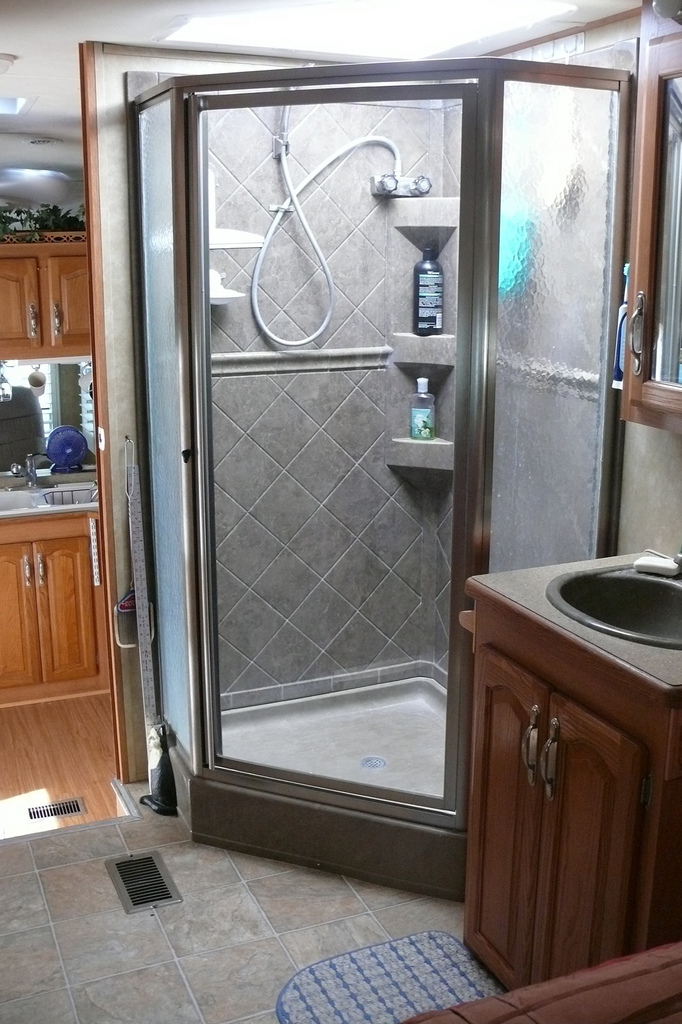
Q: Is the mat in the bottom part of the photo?
A: Yes, the mat is in the bottom of the image.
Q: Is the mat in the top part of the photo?
A: No, the mat is in the bottom of the image.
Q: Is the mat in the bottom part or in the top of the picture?
A: The mat is in the bottom of the image.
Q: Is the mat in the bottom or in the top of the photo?
A: The mat is in the bottom of the image.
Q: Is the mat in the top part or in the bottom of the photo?
A: The mat is in the bottom of the image.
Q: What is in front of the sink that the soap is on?
A: The mat is in front of the sink.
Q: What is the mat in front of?
A: The mat is in front of the sink.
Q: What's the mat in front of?
A: The mat is in front of the sink.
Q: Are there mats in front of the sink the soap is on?
A: Yes, there is a mat in front of the sink.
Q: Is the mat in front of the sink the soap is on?
A: Yes, the mat is in front of the sink.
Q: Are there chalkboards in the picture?
A: No, there are no chalkboards.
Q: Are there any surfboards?
A: No, there are no surfboards.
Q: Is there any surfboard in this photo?
A: No, there are no surfboards.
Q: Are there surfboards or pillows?
A: No, there are no surfboards or pillows.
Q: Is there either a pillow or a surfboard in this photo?
A: No, there are no surfboards or pillows.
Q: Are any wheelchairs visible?
A: No, there are no wheelchairs.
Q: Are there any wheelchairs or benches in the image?
A: No, there are no wheelchairs or benches.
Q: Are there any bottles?
A: Yes, there is a bottle.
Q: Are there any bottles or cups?
A: Yes, there is a bottle.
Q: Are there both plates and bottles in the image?
A: No, there is a bottle but no plates.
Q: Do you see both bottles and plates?
A: No, there is a bottle but no plates.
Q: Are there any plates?
A: No, there are no plates.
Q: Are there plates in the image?
A: No, there are no plates.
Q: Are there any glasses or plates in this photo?
A: No, there are no plates or glasses.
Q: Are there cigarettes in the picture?
A: No, there are no cigarettes.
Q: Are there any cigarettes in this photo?
A: No, there are no cigarettes.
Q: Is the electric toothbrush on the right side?
A: Yes, the electric toothbrush is on the right of the image.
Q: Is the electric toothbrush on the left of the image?
A: No, the electric toothbrush is on the right of the image.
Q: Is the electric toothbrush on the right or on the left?
A: The electric toothbrush is on the right of the image.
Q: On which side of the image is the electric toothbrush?
A: The electric toothbrush is on the right of the image.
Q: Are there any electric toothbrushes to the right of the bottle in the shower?
A: Yes, there is an electric toothbrush to the right of the bottle.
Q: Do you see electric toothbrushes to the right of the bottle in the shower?
A: Yes, there is an electric toothbrush to the right of the bottle.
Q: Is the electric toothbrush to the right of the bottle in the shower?
A: Yes, the electric toothbrush is to the right of the bottle.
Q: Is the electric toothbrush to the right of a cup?
A: No, the electric toothbrush is to the right of the bottle.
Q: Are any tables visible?
A: No, there are no tables.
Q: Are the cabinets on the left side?
A: Yes, the cabinets are on the left of the image.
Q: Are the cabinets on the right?
A: No, the cabinets are on the left of the image.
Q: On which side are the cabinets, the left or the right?
A: The cabinets are on the left of the image.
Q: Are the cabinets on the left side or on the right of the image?
A: The cabinets are on the left of the image.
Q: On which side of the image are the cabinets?
A: The cabinets are on the left of the image.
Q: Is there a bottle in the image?
A: Yes, there is a bottle.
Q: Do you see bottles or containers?
A: Yes, there is a bottle.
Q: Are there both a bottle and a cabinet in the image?
A: Yes, there are both a bottle and a cabinet.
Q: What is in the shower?
A: The bottle is in the shower.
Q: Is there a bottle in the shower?
A: Yes, there is a bottle in the shower.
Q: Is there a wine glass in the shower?
A: No, there is a bottle in the shower.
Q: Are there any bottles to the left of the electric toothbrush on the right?
A: Yes, there is a bottle to the left of the electric toothbrush.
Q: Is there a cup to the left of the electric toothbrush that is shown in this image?
A: No, there is a bottle to the left of the electric toothbrush.